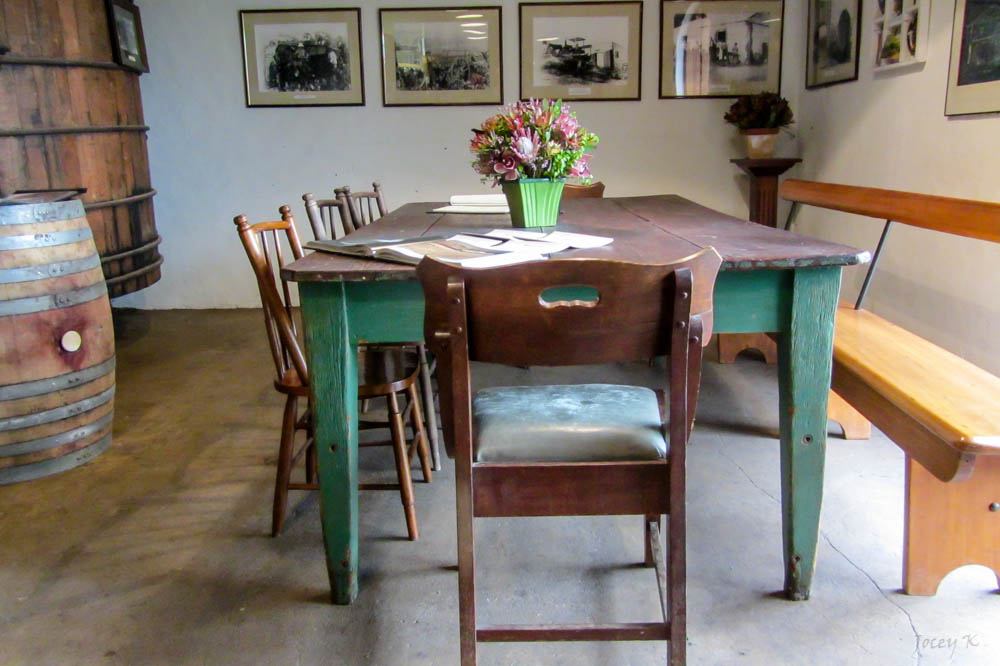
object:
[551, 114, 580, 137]
flower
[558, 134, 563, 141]
stem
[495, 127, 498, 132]
stem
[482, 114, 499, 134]
flower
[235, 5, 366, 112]
picture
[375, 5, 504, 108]
picture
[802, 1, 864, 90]
picture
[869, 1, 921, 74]
picture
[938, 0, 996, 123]
picture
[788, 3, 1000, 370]
wall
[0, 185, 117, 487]
barrel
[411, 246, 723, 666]
chair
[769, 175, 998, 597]
bench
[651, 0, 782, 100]
picture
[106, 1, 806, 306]
wall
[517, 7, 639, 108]
picture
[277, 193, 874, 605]
table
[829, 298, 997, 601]
seat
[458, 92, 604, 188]
flowers